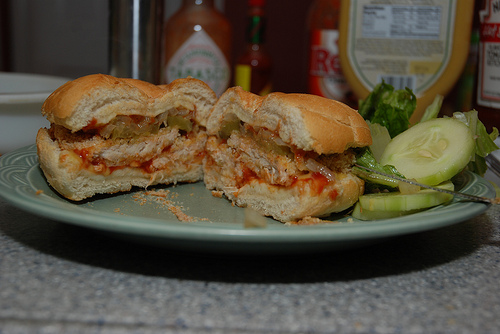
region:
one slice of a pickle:
[384, 110, 476, 183]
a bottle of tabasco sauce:
[160, 3, 232, 93]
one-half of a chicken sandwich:
[37, 73, 214, 203]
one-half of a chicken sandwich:
[205, 84, 369, 221]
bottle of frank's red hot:
[305, 7, 349, 104]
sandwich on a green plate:
[4, 74, 495, 250]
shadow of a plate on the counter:
[4, 213, 499, 285]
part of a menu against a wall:
[340, 0, 474, 132]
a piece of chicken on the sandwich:
[79, 125, 181, 165]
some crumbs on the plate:
[140, 186, 197, 225]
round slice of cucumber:
[375, 117, 480, 180]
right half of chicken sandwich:
[200, 84, 369, 221]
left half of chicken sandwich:
[36, 70, 218, 203]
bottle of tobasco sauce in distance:
[155, 0, 238, 92]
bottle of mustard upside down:
[335, 4, 482, 133]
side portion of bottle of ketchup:
[467, 1, 498, 118]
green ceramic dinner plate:
[0, 123, 499, 281]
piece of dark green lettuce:
[354, 78, 424, 135]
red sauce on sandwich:
[201, 139, 340, 208]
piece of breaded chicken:
[209, 127, 309, 182]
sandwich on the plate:
[209, 87, 368, 216]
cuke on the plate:
[387, 115, 482, 179]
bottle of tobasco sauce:
[158, 3, 230, 86]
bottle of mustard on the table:
[340, 2, 473, 97]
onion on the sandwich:
[302, 160, 337, 181]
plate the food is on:
[155, 203, 201, 234]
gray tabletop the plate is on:
[62, 263, 159, 308]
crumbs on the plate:
[140, 185, 205, 229]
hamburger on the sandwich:
[50, 124, 75, 141]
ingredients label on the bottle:
[361, 8, 440, 42]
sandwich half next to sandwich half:
[38, 73, 217, 201]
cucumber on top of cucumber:
[383, 115, 473, 182]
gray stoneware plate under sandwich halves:
[1, 139, 496, 240]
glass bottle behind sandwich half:
[165, 0, 232, 94]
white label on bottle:
[164, 28, 232, 91]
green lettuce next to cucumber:
[362, 80, 420, 134]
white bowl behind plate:
[0, 71, 74, 150]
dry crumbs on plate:
[137, 186, 210, 226]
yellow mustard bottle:
[339, 0, 471, 128]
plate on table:
[0, 163, 498, 332]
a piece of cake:
[41, 72, 218, 131]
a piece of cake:
[37, 125, 208, 201]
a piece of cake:
[204, 132, 384, 243]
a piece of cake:
[206, 66, 363, 228]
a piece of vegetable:
[370, 115, 484, 230]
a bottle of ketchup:
[161, 5, 243, 110]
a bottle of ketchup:
[340, 5, 467, 137]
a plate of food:
[6, 65, 497, 290]